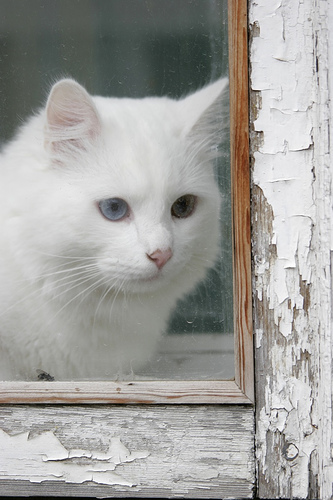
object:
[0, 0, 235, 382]
glass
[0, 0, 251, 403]
window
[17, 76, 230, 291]
head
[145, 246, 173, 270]
cat's nose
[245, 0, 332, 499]
frame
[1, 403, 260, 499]
frame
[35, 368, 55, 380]
fly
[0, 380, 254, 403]
windowsill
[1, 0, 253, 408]
frame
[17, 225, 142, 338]
whisker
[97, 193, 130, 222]
eye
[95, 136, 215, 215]
light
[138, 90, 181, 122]
wall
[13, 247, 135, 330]
whiskers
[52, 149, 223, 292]
face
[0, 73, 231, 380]
cat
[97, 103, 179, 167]
fur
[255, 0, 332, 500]
paint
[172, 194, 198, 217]
eye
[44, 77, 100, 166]
cat's ear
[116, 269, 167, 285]
mouth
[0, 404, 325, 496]
paint